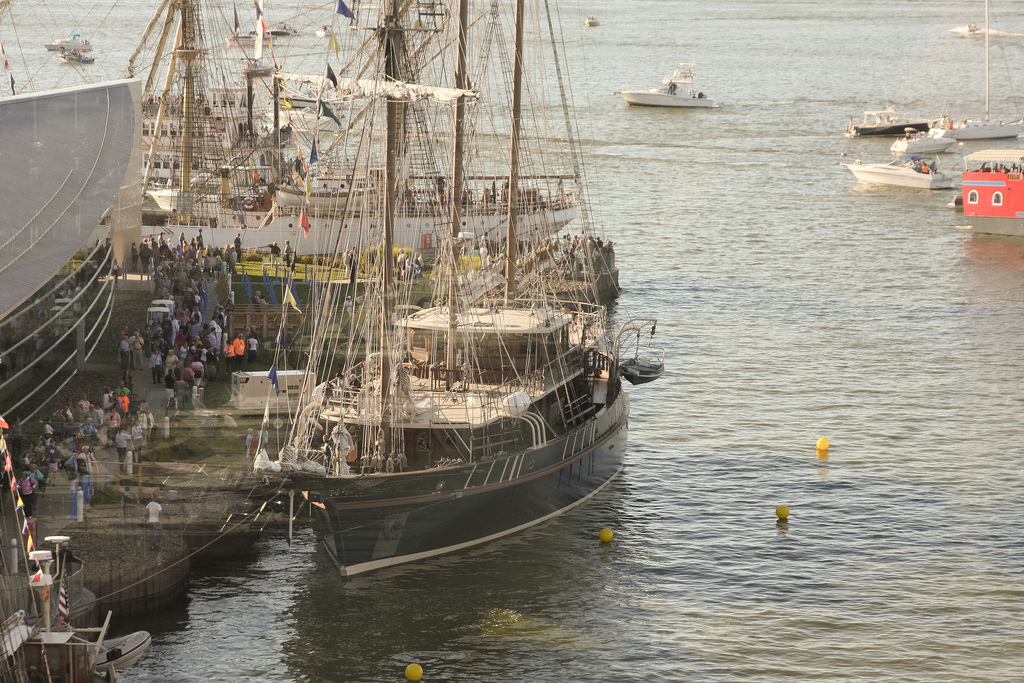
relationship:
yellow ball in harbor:
[394, 650, 424, 680] [0, 0, 1024, 683]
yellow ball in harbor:
[588, 518, 634, 545] [0, 0, 1024, 683]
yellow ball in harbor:
[770, 494, 800, 527] [0, 0, 1024, 683]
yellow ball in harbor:
[797, 428, 840, 468] [0, 0, 1024, 683]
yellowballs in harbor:
[757, 422, 833, 524] [0, 0, 1024, 683]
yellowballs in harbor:
[589, 419, 845, 553] [0, 0, 1024, 683]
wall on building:
[365, 327, 465, 452] [15, 107, 158, 421]